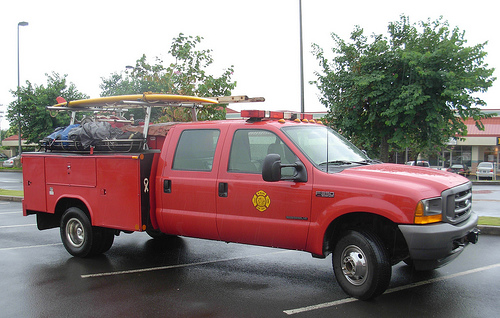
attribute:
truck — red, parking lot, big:
[12, 94, 486, 306]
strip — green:
[479, 211, 499, 228]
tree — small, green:
[316, 12, 493, 150]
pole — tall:
[12, 16, 34, 143]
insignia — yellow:
[250, 185, 273, 214]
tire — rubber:
[328, 227, 399, 305]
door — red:
[213, 124, 309, 246]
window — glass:
[171, 124, 221, 172]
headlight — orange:
[411, 191, 449, 227]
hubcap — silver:
[339, 244, 372, 288]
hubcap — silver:
[62, 217, 87, 247]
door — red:
[156, 121, 227, 243]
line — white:
[68, 249, 255, 284]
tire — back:
[54, 203, 116, 263]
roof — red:
[455, 108, 499, 133]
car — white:
[473, 160, 498, 182]